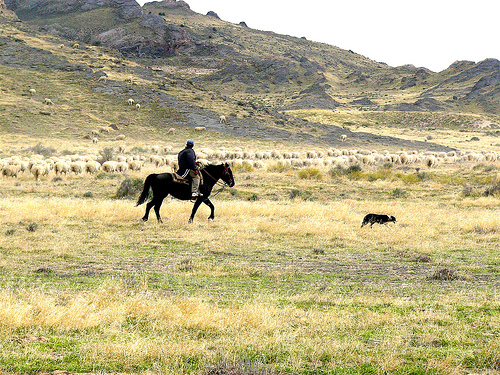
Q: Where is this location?
A: Open field.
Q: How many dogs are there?
A: One.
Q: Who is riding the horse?
A: A man.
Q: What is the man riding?
A: A horse.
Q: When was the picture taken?
A: Daytime.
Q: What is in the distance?
A: Mountain.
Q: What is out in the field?
A: Sheep.